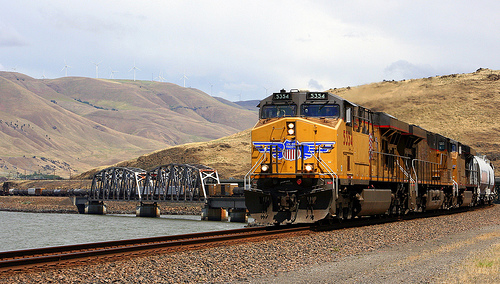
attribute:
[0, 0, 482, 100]
skies — dark gray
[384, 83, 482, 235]
person — male, slim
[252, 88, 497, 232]
train — yellow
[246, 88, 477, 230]
engine — yellow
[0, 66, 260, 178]
hills — background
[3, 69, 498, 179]
mountain — prominent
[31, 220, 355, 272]
tracks — rusty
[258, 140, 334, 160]
paint — blue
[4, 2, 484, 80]
sky — cloudy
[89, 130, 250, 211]
mountain — prominent